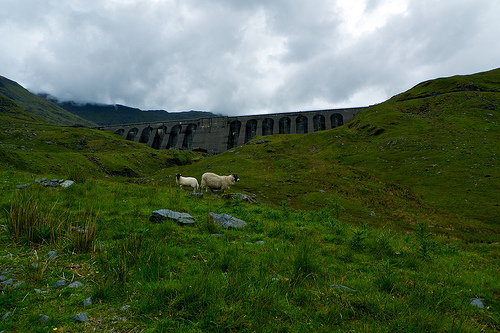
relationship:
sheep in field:
[203, 170, 237, 191] [5, 98, 493, 331]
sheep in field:
[176, 172, 201, 191] [5, 98, 493, 331]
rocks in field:
[209, 208, 248, 234] [5, 98, 493, 331]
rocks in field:
[156, 207, 195, 230] [5, 98, 493, 331]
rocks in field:
[35, 176, 72, 191] [5, 98, 493, 331]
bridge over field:
[101, 107, 364, 153] [5, 98, 493, 331]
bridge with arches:
[101, 107, 364, 153] [231, 122, 239, 149]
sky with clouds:
[2, 2, 493, 106] [228, 12, 295, 90]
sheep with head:
[203, 170, 237, 191] [233, 171, 238, 184]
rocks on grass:
[209, 208, 248, 234] [348, 142, 477, 227]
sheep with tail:
[203, 170, 237, 191] [195, 179, 201, 190]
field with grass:
[5, 98, 493, 331] [348, 142, 477, 227]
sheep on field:
[203, 170, 237, 191] [5, 98, 493, 331]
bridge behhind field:
[101, 107, 364, 153] [5, 98, 493, 331]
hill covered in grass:
[2, 75, 173, 166] [348, 142, 477, 227]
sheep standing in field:
[203, 170, 237, 191] [5, 98, 493, 331]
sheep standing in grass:
[203, 170, 237, 191] [348, 142, 477, 227]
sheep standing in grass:
[176, 172, 201, 191] [348, 142, 477, 227]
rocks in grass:
[209, 208, 248, 234] [348, 142, 477, 227]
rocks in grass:
[156, 207, 195, 230] [348, 142, 477, 227]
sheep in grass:
[203, 170, 237, 191] [348, 142, 477, 227]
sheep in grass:
[176, 172, 201, 191] [348, 142, 477, 227]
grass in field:
[348, 142, 477, 227] [5, 98, 493, 331]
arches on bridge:
[231, 122, 239, 149] [101, 107, 364, 153]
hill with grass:
[2, 75, 173, 166] [348, 142, 477, 227]